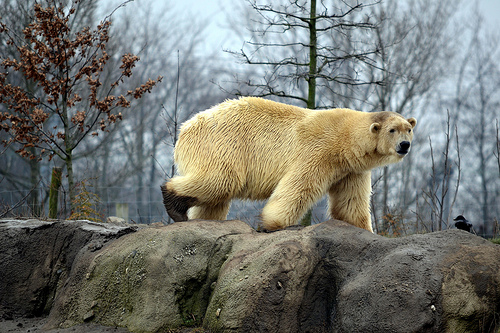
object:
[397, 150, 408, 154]
mouth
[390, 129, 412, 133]
eyes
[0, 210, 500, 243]
ground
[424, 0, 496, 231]
tree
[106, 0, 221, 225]
tree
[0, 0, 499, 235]
forest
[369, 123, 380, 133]
ear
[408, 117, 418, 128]
ear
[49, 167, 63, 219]
post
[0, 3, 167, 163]
leaves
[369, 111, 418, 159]
head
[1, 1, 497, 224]
sky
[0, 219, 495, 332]
boulder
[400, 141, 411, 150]
black nose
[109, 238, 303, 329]
wall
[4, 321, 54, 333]
ground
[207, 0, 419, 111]
bare tree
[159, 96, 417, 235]
bear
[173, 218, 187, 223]
paw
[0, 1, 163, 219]
tree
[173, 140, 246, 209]
leg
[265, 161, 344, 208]
leg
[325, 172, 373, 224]
leg